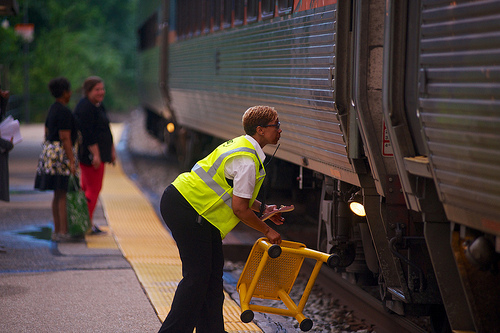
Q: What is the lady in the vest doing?
A: Providing a stool for helping someone to step off the train.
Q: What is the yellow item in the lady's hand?
A: A stool.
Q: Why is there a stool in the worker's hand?
A: To help someone exit the train.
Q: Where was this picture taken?
A: At the train station.